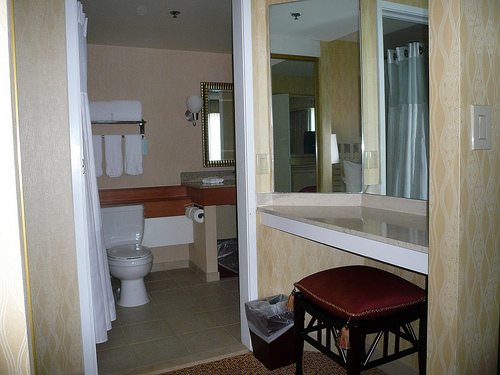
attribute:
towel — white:
[102, 133, 123, 180]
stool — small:
[288, 288, 428, 373]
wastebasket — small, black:
[242, 292, 299, 369]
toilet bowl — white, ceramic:
[106, 240, 154, 282]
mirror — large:
[267, 1, 365, 193]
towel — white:
[90, 131, 105, 177]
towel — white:
[122, 131, 144, 176]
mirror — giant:
[269, 51, 322, 191]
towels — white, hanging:
[94, 136, 151, 168]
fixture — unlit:
[169, 90, 220, 134]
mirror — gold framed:
[186, 74, 256, 163]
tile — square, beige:
[115, 279, 239, 369]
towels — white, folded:
[85, 100, 166, 130]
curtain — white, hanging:
[65, 71, 145, 334]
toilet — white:
[96, 204, 153, 309]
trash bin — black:
[241, 293, 303, 369]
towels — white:
[89, 97, 144, 119]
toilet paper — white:
[182, 201, 204, 223]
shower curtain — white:
[73, 0, 116, 340]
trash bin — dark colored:
[244, 291, 302, 364]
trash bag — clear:
[246, 293, 291, 340]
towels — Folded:
[86, 98, 140, 120]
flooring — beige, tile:
[100, 259, 240, 373]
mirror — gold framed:
[202, 83, 233, 164]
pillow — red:
[301, 262, 425, 313]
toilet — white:
[92, 199, 158, 309]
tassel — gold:
[334, 312, 353, 353]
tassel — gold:
[277, 279, 299, 319]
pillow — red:
[285, 264, 427, 349]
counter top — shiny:
[258, 186, 437, 256]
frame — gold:
[199, 78, 236, 168]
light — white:
[182, 88, 203, 128]